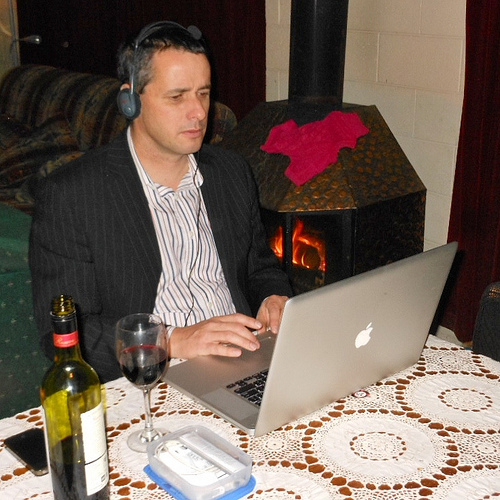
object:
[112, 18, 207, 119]
headphone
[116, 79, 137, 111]
ear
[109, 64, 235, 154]
couch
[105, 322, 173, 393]
glass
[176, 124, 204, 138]
mouth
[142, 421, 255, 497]
container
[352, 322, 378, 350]
apple logo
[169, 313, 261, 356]
hand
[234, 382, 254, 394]
key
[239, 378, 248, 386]
key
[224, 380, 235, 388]
key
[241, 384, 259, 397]
key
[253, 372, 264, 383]
key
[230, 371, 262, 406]
keyboard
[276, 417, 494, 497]
tablecloth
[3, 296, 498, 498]
table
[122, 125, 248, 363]
shirt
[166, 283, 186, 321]
stripe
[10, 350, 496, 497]
table cloth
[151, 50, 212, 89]
forehead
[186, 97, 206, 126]
nose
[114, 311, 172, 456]
glass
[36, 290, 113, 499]
bottle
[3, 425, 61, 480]
phone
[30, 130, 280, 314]
suit jacket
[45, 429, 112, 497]
wine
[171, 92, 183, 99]
eye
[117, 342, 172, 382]
liquid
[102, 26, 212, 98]
hair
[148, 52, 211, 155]
face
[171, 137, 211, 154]
chin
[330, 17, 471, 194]
wall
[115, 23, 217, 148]
head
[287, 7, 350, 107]
pipe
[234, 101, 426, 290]
fireplace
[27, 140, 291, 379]
outfit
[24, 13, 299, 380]
man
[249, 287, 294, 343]
hand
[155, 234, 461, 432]
laptop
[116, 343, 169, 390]
wine